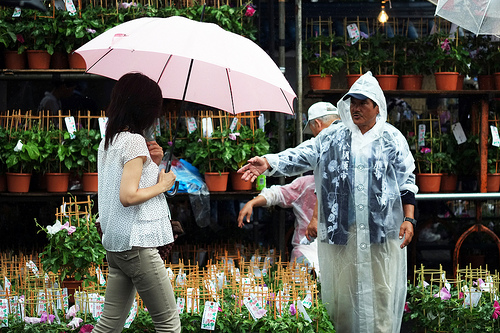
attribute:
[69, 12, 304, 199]
umbrella — pink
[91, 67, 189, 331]
woman — walking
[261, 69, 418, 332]
parka — plastic, clear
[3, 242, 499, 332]
plants — sitting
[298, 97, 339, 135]
hat — white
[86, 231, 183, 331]
pants — gray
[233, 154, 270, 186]
hand — up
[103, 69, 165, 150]
hair — black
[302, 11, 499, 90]
plants — displayed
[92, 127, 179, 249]
blouse — white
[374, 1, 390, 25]
light buld — hanging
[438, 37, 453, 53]
flower — pink